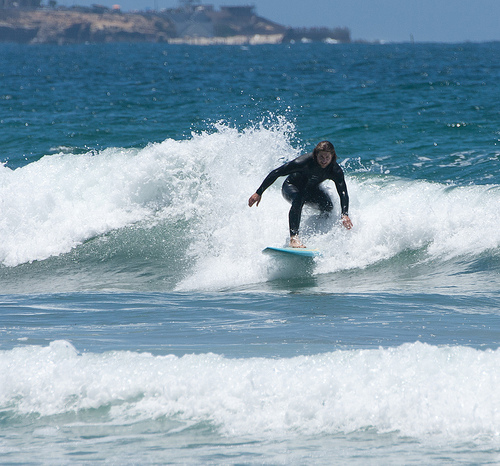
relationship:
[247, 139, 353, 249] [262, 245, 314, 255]
man riding surfboard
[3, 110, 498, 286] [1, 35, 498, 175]
white wave on blue water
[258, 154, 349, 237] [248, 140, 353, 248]
suit on woman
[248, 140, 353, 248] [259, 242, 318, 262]
woman on surf board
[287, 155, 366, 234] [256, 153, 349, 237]
woman wearing suit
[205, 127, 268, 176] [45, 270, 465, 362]
wave on water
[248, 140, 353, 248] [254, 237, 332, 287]
woman crouching over surfboard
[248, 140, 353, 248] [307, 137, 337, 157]
woman with blonde hair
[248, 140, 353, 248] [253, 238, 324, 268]
woman on surfboard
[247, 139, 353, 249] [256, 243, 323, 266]
man riding surfboard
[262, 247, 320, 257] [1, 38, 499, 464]
surf board in water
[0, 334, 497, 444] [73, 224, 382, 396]
foam on water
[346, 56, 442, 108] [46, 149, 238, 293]
blue water behind wave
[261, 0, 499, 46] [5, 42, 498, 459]
cloudless sky over ocean